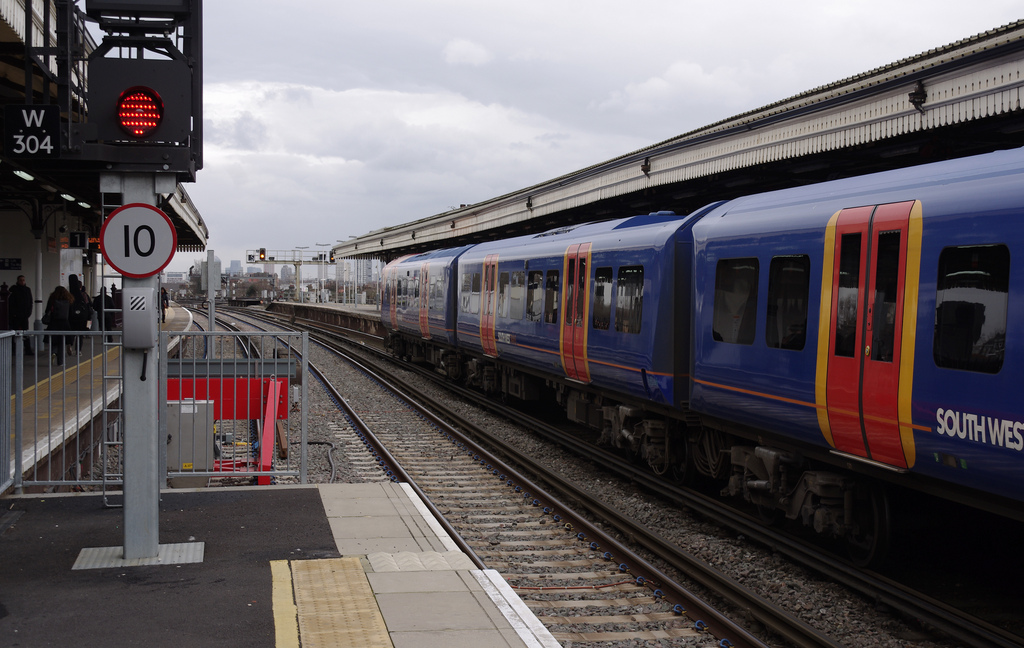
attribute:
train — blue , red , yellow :
[259, 160, 905, 603]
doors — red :
[790, 167, 916, 494]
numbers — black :
[110, 195, 180, 301]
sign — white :
[78, 143, 279, 634]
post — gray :
[39, 163, 254, 593]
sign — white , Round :
[88, 160, 214, 344]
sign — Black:
[77, 35, 240, 329]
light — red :
[92, 53, 240, 188]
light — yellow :
[32, 31, 551, 466]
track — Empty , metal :
[343, 316, 750, 600]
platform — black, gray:
[63, 480, 310, 638]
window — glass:
[917, 208, 995, 327]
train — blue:
[621, 223, 948, 567]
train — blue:
[566, 255, 839, 390]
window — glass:
[780, 186, 884, 385]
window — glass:
[647, 247, 756, 382]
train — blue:
[519, 199, 921, 454]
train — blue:
[582, 245, 859, 433]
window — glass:
[564, 251, 705, 385]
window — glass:
[571, 243, 638, 391]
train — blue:
[448, 227, 729, 415]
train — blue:
[418, 236, 708, 418]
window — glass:
[538, 214, 651, 375]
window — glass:
[398, 219, 559, 412]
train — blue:
[573, 158, 822, 521]